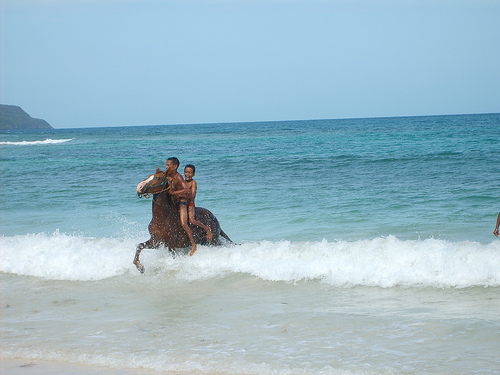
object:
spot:
[142, 174, 155, 183]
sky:
[0, 2, 499, 129]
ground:
[438, 162, 481, 193]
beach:
[0, 274, 500, 373]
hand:
[493, 228, 499, 237]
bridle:
[140, 172, 171, 203]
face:
[140, 172, 163, 188]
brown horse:
[133, 167, 232, 273]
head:
[137, 167, 172, 194]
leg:
[133, 237, 160, 263]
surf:
[0, 229, 499, 289]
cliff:
[0, 105, 52, 130]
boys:
[166, 157, 212, 257]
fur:
[145, 174, 158, 189]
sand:
[0, 351, 193, 375]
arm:
[496, 212, 500, 229]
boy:
[184, 164, 212, 242]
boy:
[166, 157, 196, 256]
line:
[0, 258, 500, 291]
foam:
[0, 137, 75, 146]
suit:
[188, 203, 195, 207]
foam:
[0, 229, 500, 290]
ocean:
[0, 112, 500, 374]